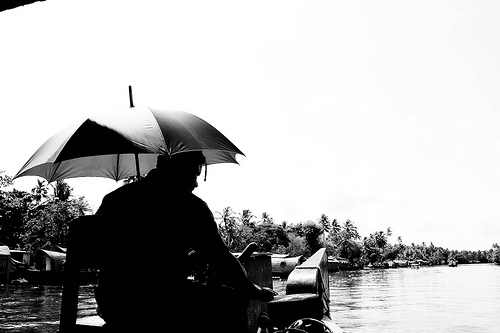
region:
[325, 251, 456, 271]
Houses along the water line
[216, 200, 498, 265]
Trees growing along the water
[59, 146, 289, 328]
Man sitting on a boat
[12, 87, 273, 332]
Man sitting under an umbrella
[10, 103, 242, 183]
Umbrella shading the man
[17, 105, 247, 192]
Black and white umbrella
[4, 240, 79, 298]
Houses along the water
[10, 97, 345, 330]
Man sitting under umbrella on a boat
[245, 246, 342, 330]
Front of boat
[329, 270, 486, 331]
water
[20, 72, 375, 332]
a person sitting next to the river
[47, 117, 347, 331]
a man under an umbrella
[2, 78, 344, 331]
a man holding an umbrella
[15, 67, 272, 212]
an umbrella with multiple shades of color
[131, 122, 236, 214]
a man looking at the water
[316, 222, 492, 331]
a body of water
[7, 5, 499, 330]
a scene happening outdoors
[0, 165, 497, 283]
a row of trees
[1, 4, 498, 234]
a cloudy sky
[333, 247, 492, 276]
couple of dwellings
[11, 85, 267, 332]
Man on boat holding umbrella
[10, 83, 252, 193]
Umbrella over man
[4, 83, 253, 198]
Umbrella giving man shade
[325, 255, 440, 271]
Homes along water line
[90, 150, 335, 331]
Man riding on boat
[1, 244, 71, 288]
Homes along the water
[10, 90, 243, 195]
Black and white umbrella over man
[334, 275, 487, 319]
Open water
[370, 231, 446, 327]
the water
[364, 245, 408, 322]
the water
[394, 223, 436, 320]
the water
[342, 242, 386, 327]
the water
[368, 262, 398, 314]
the water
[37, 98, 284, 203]
Open umbrella with stripes.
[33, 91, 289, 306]
Man holding the umbrella.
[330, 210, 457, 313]
Water with trees by it.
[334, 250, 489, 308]
Ripples in the water.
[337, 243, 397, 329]
Reflections on the water.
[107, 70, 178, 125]
Spoke on the umbrella.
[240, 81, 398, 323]
Sky above the water.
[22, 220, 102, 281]
Building behind the man.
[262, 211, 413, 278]
Trees by the buildings.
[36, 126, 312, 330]
Man who is sitting.